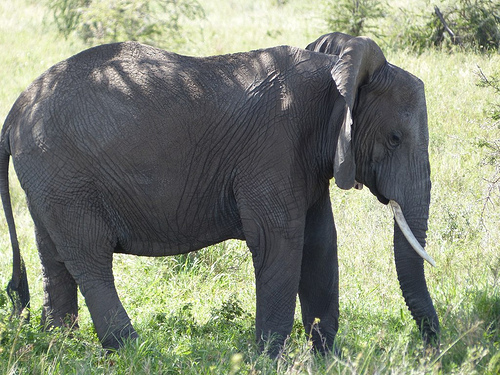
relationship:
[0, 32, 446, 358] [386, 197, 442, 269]
elephant has tusk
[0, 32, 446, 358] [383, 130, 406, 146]
elephant has eye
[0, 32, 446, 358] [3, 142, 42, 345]
elephant has tail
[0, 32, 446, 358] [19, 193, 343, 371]
elephant has legs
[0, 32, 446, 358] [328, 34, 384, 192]
elephant has ear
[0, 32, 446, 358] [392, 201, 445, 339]
elephant with trunk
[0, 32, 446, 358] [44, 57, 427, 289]
elephant has wrinkles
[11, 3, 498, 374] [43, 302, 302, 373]
grass growing around feet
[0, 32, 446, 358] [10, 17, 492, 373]
elephant in field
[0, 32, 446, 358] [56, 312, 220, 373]
elephant on grass